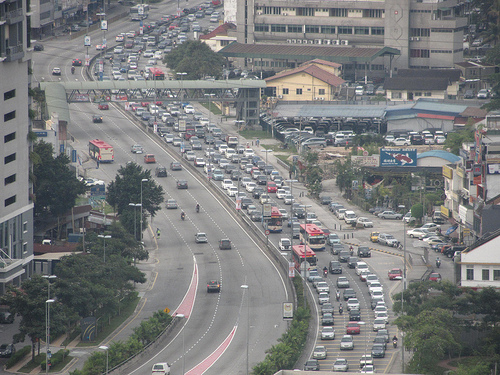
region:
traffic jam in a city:
[40, 17, 469, 362]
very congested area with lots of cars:
[168, 125, 486, 317]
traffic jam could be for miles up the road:
[79, 10, 410, 371]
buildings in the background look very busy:
[263, 51, 498, 229]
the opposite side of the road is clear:
[30, 14, 284, 373]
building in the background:
[2, 1, 77, 321]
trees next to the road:
[16, 145, 279, 359]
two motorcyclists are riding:
[161, 190, 232, 255]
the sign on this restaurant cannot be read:
[363, 131, 480, 231]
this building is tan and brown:
[253, 38, 350, 133]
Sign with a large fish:
[366, 141, 425, 175]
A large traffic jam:
[88, 0, 400, 374]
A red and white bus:
[78, 133, 128, 175]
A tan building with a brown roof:
[246, 52, 346, 121]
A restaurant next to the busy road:
[343, 137, 473, 217]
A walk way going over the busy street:
[28, 61, 290, 152]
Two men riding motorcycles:
[167, 198, 210, 229]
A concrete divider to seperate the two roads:
[75, 1, 309, 373]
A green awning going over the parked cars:
[258, 96, 388, 141]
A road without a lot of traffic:
[15, 0, 292, 374]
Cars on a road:
[154, 121, 348, 320]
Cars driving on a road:
[112, 130, 225, 261]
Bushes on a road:
[268, 283, 325, 369]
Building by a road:
[342, 118, 477, 238]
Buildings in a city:
[261, 82, 499, 298]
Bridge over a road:
[50, 69, 298, 128]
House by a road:
[260, 40, 348, 131]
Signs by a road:
[71, 16, 144, 87]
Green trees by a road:
[37, 235, 171, 341]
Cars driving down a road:
[74, 37, 251, 174]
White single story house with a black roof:
[383, 75, 445, 102]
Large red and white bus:
[298, 221, 325, 249]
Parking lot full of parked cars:
[276, 117, 375, 144]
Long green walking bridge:
[66, 81, 263, 102]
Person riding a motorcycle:
[391, 332, 398, 348]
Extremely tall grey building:
[0, 1, 32, 284]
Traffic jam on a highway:
[191, 121, 279, 195]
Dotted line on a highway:
[192, 311, 224, 336]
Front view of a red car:
[345, 318, 362, 333]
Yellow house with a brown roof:
[273, 60, 344, 100]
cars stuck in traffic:
[110, 55, 378, 374]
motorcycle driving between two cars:
[317, 260, 339, 278]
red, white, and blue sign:
[378, 140, 421, 169]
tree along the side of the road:
[102, 156, 163, 235]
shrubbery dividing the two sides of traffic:
[252, 298, 311, 374]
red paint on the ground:
[188, 322, 248, 373]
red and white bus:
[82, 133, 117, 169]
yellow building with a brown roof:
[256, 48, 345, 104]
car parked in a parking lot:
[378, 205, 400, 223]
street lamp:
[36, 269, 62, 373]